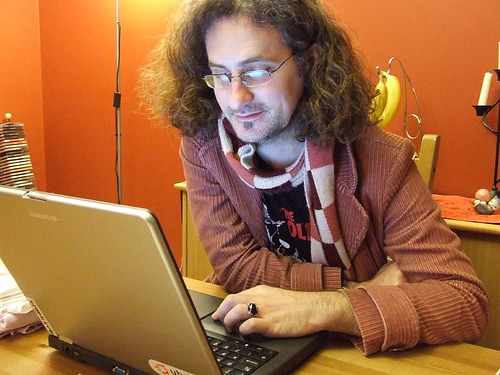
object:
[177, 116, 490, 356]
jacket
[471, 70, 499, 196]
candelabra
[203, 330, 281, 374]
keyboard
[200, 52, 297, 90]
eyeglasses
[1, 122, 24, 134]
compact discs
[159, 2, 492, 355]
man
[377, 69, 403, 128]
banana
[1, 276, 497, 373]
wood grain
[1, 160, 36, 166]
cds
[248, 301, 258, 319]
black ring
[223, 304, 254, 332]
finger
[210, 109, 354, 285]
scarf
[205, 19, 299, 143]
face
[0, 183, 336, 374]
laptop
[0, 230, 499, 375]
desk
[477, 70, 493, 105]
candle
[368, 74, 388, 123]
bananas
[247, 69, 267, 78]
eyes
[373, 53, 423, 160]
rack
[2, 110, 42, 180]
these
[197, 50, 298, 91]
pair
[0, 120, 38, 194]
stack